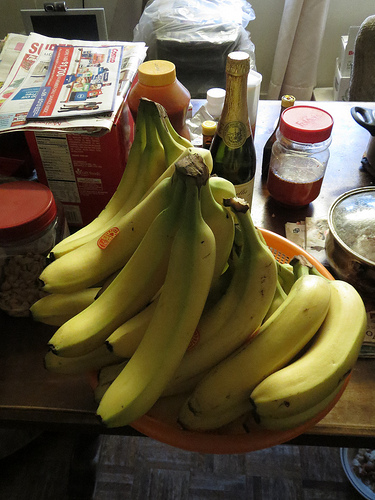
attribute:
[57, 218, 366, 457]
basket — orange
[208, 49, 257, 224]
bottle — unopened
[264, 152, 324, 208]
liquid — red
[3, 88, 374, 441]
table — wooden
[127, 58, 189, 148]
bottle — squeeze bottle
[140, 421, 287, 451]
bowl — Orange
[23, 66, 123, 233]
box — red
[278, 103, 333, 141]
cap — red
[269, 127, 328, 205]
jar — glass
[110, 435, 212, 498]
tile — brown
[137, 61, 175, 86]
lid — yellow